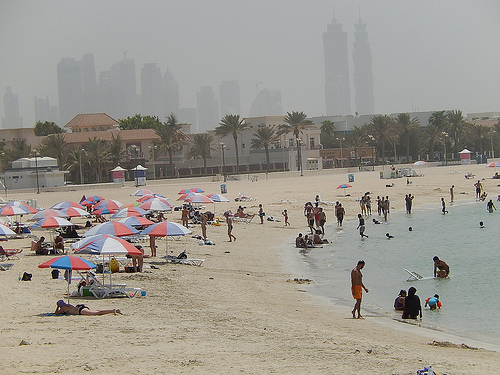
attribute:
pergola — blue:
[126, 157, 156, 188]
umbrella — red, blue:
[56, 236, 163, 296]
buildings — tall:
[24, 39, 288, 139]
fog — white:
[1, 8, 493, 115]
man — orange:
[347, 260, 369, 315]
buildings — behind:
[15, 12, 433, 118]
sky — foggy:
[0, 1, 497, 130]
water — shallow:
[303, 190, 498, 336]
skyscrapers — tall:
[321, 7, 376, 117]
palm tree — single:
[217, 115, 259, 157]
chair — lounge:
[397, 266, 449, 289]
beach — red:
[93, 164, 426, 372]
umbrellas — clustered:
[4, 194, 211, 280]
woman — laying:
[53, 300, 123, 316]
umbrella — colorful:
[35, 252, 100, 296]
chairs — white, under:
[67, 266, 153, 323]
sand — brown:
[235, 226, 260, 349]